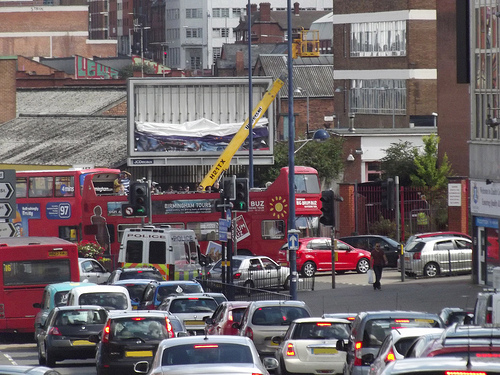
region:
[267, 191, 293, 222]
a yellow sun on the bus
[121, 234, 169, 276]
rear doors on the police van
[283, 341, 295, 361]
a red tail light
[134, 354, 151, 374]
a side view mirror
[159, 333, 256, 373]
a rear window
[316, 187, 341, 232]
a bank of traffic lights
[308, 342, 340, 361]
a yellow license plate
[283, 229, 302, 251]
a blue street sign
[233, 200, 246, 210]
a green traffic light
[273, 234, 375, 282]
a red car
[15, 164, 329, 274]
two double-decker buses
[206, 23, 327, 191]
a yellow crane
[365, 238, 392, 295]
a person on the sidewalk holding a bag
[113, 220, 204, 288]
a white police van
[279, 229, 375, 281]
a red compact car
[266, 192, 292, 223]
a logo of a yellow sun on the red bus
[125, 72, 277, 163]
a billboard that is being switched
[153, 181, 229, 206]
people sitting on the top level of the bus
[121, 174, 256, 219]
two green traffic signals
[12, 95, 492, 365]
a busy city intersection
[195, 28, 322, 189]
The large yellow crane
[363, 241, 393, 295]
The man shown walking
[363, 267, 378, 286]
The white bag held by the man walking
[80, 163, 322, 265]
The bus in front of the yellow crane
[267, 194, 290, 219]
The sun on the side of a bus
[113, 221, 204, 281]
The police van in traffic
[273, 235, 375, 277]
The red car behind the walking man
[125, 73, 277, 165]
The billboard with the missing sign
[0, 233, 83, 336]
The small red bus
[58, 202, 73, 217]
The 97 on the side of a bus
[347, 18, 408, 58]
windows of a building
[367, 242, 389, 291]
a man carrying a white bag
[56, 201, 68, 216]
the number 97 can be seen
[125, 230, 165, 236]
the word police can be seen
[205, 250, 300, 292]
a small silver car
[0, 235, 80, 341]
a red bus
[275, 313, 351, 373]
a white car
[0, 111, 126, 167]
the roof of a building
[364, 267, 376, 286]
a white bag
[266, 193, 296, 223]
Sun painted on bus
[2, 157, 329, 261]
Double decker buses on the road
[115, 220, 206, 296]
Police vehicle in traffic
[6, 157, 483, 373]
Very busy street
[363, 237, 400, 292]
Person walking on sidewalk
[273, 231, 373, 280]
Red car in an intersection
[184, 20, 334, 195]
Yellow construction equiptment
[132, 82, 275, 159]
Billboard is crumpled up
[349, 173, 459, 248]
Red metal fence in front of building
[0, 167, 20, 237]
Black and white road signd